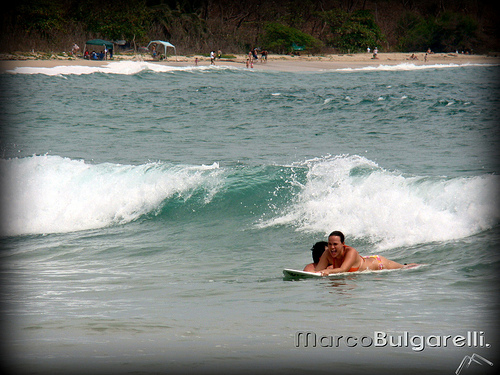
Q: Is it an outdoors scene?
A: Yes, it is outdoors.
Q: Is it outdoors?
A: Yes, it is outdoors.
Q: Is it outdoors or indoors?
A: It is outdoors.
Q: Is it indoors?
A: No, it is outdoors.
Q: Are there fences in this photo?
A: No, there are no fences.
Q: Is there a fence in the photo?
A: No, there are no fences.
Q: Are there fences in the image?
A: No, there are no fences.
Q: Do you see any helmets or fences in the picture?
A: No, there are no fences or helmets.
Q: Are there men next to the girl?
A: Yes, there is a man next to the girl.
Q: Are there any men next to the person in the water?
A: Yes, there is a man next to the girl.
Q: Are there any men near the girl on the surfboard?
A: Yes, there is a man near the girl.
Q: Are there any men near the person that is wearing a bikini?
A: Yes, there is a man near the girl.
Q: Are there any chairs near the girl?
A: No, there is a man near the girl.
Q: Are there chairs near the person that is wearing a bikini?
A: No, there is a man near the girl.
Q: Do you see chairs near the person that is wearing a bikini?
A: No, there is a man near the girl.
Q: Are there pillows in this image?
A: No, there are no pillows.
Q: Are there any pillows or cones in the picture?
A: No, there are no pillows or cones.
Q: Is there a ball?
A: No, there are no balls.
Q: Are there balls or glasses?
A: No, there are no balls or glasses.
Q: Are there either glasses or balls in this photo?
A: No, there are no balls or glasses.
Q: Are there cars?
A: No, there are no cars.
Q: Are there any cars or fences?
A: No, there are no cars or fences.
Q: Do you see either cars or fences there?
A: No, there are no cars or fences.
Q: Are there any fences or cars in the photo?
A: No, there are no cars or fences.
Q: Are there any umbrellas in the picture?
A: No, there are no umbrellas.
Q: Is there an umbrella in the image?
A: No, there are no umbrellas.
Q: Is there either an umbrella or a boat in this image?
A: No, there are no umbrellas or boats.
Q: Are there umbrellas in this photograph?
A: No, there are no umbrellas.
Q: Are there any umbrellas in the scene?
A: No, there are no umbrellas.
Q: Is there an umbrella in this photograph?
A: No, there are no umbrellas.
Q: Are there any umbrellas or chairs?
A: No, there are no umbrellas or chairs.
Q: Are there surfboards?
A: Yes, there is a surfboard.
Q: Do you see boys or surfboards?
A: Yes, there is a surfboard.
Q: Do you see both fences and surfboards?
A: No, there is a surfboard but no fences.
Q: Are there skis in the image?
A: No, there are no skis.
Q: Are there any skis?
A: No, there are no skis.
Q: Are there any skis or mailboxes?
A: No, there are no skis or mailboxes.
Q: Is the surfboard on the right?
A: Yes, the surfboard is on the right of the image.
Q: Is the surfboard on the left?
A: No, the surfboard is on the right of the image.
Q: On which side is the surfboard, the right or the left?
A: The surfboard is on the right of the image.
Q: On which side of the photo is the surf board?
A: The surf board is on the right of the image.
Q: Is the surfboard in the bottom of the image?
A: Yes, the surfboard is in the bottom of the image.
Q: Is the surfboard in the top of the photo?
A: No, the surfboard is in the bottom of the image.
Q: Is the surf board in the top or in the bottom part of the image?
A: The surf board is in the bottom of the image.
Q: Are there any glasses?
A: No, there are no glasses.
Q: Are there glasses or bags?
A: No, there are no glasses or bags.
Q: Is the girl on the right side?
A: Yes, the girl is on the right of the image.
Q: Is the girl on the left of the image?
A: No, the girl is on the right of the image.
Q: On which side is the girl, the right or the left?
A: The girl is on the right of the image.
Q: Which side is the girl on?
A: The girl is on the right of the image.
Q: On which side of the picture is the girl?
A: The girl is on the right of the image.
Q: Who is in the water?
A: The girl is in the water.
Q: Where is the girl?
A: The girl is in the water.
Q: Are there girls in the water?
A: Yes, there is a girl in the water.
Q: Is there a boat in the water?
A: No, there is a girl in the water.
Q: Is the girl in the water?
A: Yes, the girl is in the water.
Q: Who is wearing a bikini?
A: The girl is wearing a bikini.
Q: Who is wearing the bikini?
A: The girl is wearing a bikini.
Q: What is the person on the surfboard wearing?
A: The girl is wearing a bikini.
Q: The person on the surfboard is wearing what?
A: The girl is wearing a bikini.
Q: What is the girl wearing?
A: The girl is wearing a bikini.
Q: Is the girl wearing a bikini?
A: Yes, the girl is wearing a bikini.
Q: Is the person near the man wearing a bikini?
A: Yes, the girl is wearing a bikini.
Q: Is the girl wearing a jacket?
A: No, the girl is wearing a bikini.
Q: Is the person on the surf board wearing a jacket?
A: No, the girl is wearing a bikini.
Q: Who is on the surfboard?
A: The girl is on the surfboard.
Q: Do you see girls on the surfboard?
A: Yes, there is a girl on the surfboard.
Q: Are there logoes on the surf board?
A: No, there is a girl on the surf board.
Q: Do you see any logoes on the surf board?
A: No, there is a girl on the surf board.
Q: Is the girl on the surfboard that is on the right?
A: Yes, the girl is on the surf board.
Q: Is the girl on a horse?
A: No, the girl is on the surf board.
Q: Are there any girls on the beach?
A: Yes, there is a girl on the beach.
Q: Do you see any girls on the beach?
A: Yes, there is a girl on the beach.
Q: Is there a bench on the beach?
A: No, there is a girl on the beach.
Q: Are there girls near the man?
A: Yes, there is a girl near the man.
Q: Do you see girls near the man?
A: Yes, there is a girl near the man.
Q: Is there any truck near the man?
A: No, there is a girl near the man.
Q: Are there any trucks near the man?
A: No, there is a girl near the man.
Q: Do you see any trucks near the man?
A: No, there is a girl near the man.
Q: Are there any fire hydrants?
A: No, there are no fire hydrants.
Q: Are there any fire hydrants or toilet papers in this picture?
A: No, there are no fire hydrants or toilet papers.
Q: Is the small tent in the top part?
A: Yes, the tent is in the top of the image.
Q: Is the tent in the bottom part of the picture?
A: No, the tent is in the top of the image.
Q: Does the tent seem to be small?
A: Yes, the tent is small.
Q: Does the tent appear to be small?
A: Yes, the tent is small.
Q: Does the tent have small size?
A: Yes, the tent is small.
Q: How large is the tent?
A: The tent is small.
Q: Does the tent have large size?
A: No, the tent is small.